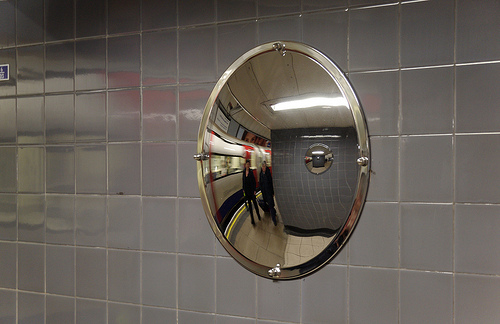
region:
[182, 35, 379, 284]
a convex silver mirror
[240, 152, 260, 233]
a woman reflected in the mirror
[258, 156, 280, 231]
a man reflected in the mirror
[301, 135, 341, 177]
a reflection of a mirror in a mirror in a mirror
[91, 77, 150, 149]
a blue wall tile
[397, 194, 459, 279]
a blue wall tile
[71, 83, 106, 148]
a blue wall tile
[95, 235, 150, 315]
a blue wall tile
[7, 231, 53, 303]
a blue wall tile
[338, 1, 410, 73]
a blue wall tile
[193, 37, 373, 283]
a mirror reflects two travellers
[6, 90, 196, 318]
grey ceramic tile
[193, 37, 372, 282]
a reflection of a subway station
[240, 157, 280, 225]
two travelers dressed in black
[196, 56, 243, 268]
reflection of a subway car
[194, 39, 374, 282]
a round mirror in a subway station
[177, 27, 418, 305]
a round mirror set against grey square tiles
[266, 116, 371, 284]
a mirror on a tile wall reflecting a mirror on a tile wall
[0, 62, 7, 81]
small blue sign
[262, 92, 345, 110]
reflection of a flurescent light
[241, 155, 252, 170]
Person has dark hair.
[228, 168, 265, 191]
Person wearing black shirt.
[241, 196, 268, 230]
Person wearing black pants.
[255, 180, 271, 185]
Person wearing black coat.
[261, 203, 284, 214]
Person wearing dark pants.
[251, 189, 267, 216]
Person pulling suitcase.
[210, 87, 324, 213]
Round mirror attached to mirror.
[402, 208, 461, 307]
Gray tile on wall.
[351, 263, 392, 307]
Gray tile on wall.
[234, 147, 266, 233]
This is a person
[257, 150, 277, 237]
This is a person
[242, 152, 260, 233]
This is a person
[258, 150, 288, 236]
This is a person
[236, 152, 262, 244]
This is a person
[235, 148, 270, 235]
This is a person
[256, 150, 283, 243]
This is a person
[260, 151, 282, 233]
This is a person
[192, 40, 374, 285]
a mirror attached to the wall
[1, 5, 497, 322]
a wall covered in bluish gray tiles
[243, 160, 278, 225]
a reflection of people in the mirror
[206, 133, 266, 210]
a red and white train on the track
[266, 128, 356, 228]
a reflection of the wall and the mirror.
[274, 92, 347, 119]
a light in the ceiling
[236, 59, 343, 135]
the ceiling the light is attached too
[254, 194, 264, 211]
a suitcase being carred by a person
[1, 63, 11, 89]
a little sign on the wall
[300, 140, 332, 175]
the mirror being reflected in a mirror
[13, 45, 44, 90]
a tile in a wall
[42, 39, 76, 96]
a tile in a wall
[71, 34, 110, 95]
a tile in a wall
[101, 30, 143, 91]
a tile in a wall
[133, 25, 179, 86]
a tile in a wall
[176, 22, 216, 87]
a tile in a wall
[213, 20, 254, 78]
a tile in a wall